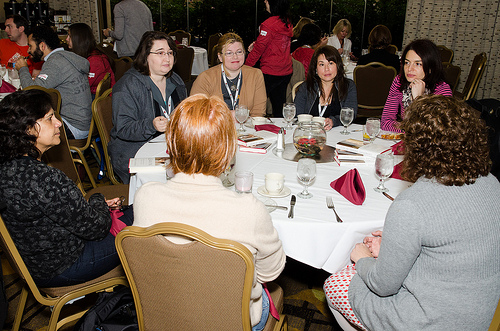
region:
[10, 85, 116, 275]
PERSON SITTING AT DINNER TABLE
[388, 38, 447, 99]
PERSON SITTING AT DINNER TABLE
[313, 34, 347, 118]
PERSON SITTING AT DINNER TABLE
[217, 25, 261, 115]
PERSON SITTING AT DINNER TABLE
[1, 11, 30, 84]
PERSON SITTING AT DINNER TABLE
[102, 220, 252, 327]
back of a cream chair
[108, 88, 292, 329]
the back of a lady on a chair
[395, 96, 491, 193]
medium length curly brown hair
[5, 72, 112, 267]
woman wearing a black and gray blouse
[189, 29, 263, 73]
woman with red lipstick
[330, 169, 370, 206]
red napkin folded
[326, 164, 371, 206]
red napkin folded on the table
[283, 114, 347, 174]
clear round jar on the table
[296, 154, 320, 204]
clear wine glass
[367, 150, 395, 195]
wine glass filled with water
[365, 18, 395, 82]
Woman sitting at a table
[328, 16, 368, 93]
Woman sitting at a table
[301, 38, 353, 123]
Woman sitting at a table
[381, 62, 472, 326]
Woman sitting at a table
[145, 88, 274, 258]
Woman sitting at a table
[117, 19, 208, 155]
Woman sitting at a table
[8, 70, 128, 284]
Woman sitting at a table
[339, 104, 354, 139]
small cup sitting on table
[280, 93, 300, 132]
small cup sitting on table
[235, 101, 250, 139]
small cup sitting on table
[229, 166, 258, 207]
small cup sitting on table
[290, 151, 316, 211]
small cup sitting on table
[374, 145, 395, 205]
small cup sitting on table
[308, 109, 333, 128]
small cup sitting on table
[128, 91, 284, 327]
woman sits at dinner table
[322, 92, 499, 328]
woman sits at dinner table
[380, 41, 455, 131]
woman sits at dinner table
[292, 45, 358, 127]
woman sits at dinner table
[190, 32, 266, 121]
woman sits at dinner table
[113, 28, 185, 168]
woman sits at dinner table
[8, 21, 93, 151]
man sits at dinner table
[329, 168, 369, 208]
napkin is folded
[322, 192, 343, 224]
fork sits on table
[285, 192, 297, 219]
knife sits on table